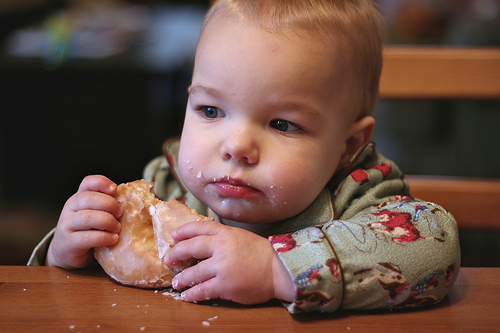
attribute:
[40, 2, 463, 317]
kid — young, staring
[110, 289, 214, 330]
crumbs — scattered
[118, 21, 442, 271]
baby — eating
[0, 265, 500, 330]
table — wood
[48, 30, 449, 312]
baby — eating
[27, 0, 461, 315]
baby — leaning, dirty blonde, sitting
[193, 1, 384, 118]
hair — dusty blond